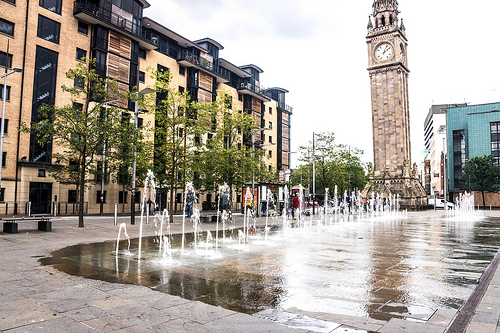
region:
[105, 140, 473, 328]
this is a water fountain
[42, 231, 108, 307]
the ground is wet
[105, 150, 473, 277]
the water is up in the air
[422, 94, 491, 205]
a blue building next to clock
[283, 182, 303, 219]
this is a person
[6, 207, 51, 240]
a bench next to the fountain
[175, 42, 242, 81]
a balcony on the side of the building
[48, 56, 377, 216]
trees next to fountain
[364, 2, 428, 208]
a tal clock tower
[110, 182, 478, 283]
a fountain in the middle of a square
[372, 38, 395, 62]
a round white clock face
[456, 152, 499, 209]
a treenext to a building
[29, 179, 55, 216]
a dark glass double door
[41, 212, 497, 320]
wet stones around a fountain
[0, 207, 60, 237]
a bench near a fountain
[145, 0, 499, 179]
a bright white sky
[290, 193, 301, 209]
a red top on a person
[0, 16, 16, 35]
a window in a building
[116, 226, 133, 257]
water spouting out from ground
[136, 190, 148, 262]
water spouting out from ground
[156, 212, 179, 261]
water spouting out from ground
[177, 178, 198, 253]
water spouting out from ground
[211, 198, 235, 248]
water spouting out from ground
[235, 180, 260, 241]
water spouting out from ground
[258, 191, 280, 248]
water spouting out from ground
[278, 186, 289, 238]
water spouting out from ground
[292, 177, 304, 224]
water spouting out from ground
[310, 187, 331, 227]
water spouting out from ground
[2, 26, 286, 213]
building in the photo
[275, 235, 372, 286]
wet ground in the photo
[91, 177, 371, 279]
water in the photo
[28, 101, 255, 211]
trees next to the people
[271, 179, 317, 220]
people on the ground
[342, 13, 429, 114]
clock tower in the photo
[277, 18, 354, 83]
sky above the land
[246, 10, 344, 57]
clouds in the sky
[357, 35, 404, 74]
round clock in photo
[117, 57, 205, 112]
windows on the building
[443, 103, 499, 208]
tall blue apartment building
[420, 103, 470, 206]
white and grey tall building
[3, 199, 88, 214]
black wrought iron fence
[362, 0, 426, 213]
tall brown clock tower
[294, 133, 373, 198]
small clump of green trees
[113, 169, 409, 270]
white curved sprays of water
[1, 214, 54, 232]
small cement bench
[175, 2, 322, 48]
collection of dark grey clouds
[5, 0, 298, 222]
large tan and black apartment building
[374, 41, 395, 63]
white and black clock face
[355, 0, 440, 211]
a large clock tower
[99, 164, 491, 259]
fountains in a plaza area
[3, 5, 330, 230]
large building along side of plaza area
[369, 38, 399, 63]
large clock face on tower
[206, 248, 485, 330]
water from fountains draining on stones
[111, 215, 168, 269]
water squirting up from ground level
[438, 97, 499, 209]
an aqua colored building in the distance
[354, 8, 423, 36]
ornated spires near top of clock tower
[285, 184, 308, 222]
people walking near the fountains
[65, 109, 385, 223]
trees and light poles along open plaza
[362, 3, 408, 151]
black and white clock in tan tower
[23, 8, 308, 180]
tan and brown building